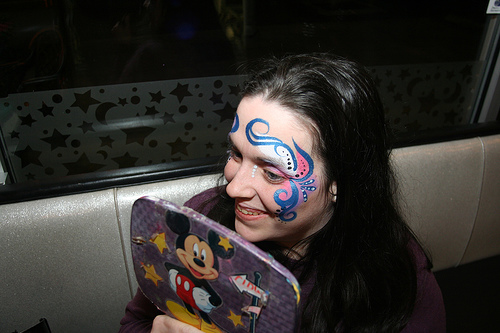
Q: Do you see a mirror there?
A: Yes, there is a mirror.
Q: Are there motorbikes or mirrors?
A: Yes, there is a mirror.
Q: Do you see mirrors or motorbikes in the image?
A: Yes, there is a mirror.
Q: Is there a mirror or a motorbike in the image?
A: Yes, there is a mirror.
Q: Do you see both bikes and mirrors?
A: No, there is a mirror but no bikes.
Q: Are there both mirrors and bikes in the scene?
A: No, there is a mirror but no bikes.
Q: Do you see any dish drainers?
A: No, there are no dish drainers.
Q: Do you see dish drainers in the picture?
A: No, there are no dish drainers.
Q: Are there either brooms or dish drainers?
A: No, there are no dish drainers or brooms.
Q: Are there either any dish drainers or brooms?
A: No, there are no dish drainers or brooms.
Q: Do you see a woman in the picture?
A: Yes, there is a woman.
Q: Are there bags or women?
A: Yes, there is a woman.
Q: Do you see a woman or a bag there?
A: Yes, there is a woman.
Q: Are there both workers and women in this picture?
A: No, there is a woman but no workers.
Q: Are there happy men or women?
A: Yes, there is a happy woman.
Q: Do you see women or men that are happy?
A: Yes, the woman is happy.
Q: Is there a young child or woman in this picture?
A: Yes, there is a young woman.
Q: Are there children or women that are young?
A: Yes, the woman is young.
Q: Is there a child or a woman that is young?
A: Yes, the woman is young.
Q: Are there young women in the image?
A: Yes, there is a young woman.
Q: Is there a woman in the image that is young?
A: Yes, there is a woman that is young.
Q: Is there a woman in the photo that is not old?
A: Yes, there is an young woman.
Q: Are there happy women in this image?
A: Yes, there is a happy woman.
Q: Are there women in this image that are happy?
A: Yes, there is a woman that is happy.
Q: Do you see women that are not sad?
A: Yes, there is a happy woman.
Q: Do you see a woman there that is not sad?
A: Yes, there is a happy woman.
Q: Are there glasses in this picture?
A: No, there are no glasses.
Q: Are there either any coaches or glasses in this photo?
A: No, there are no glasses or coaches.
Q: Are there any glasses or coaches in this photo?
A: No, there are no glasses or coaches.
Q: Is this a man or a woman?
A: This is a woman.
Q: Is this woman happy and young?
A: Yes, the woman is happy and young.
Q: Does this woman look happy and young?
A: Yes, the woman is happy and young.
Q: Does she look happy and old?
A: No, the woman is happy but young.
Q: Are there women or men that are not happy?
A: No, there is a woman but she is happy.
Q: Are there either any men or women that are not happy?
A: No, there is a woman but she is happy.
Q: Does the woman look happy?
A: Yes, the woman is happy.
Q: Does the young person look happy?
A: Yes, the woman is happy.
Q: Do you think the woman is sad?
A: No, the woman is happy.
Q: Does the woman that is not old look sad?
A: No, the woman is happy.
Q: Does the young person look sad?
A: No, the woman is happy.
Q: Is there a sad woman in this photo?
A: No, there is a woman but she is happy.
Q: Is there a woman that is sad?
A: No, there is a woman but she is happy.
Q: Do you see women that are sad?
A: No, there is a woman but she is happy.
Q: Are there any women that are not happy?
A: No, there is a woman but she is happy.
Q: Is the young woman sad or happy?
A: The woman is happy.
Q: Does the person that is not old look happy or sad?
A: The woman is happy.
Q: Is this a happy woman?
A: Yes, this is a happy woman.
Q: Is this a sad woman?
A: No, this is a happy woman.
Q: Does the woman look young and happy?
A: Yes, the woman is young and happy.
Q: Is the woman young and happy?
A: Yes, the woman is young and happy.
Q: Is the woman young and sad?
A: No, the woman is young but happy.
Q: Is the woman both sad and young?
A: No, the woman is young but happy.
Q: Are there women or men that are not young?
A: No, there is a woman but she is young.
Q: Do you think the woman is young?
A: Yes, the woman is young.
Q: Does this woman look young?
A: Yes, the woman is young.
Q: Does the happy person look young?
A: Yes, the woman is young.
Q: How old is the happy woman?
A: The woman is young.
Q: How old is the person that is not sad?
A: The woman is young.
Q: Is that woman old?
A: No, the woman is young.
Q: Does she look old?
A: No, the woman is young.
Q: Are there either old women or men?
A: No, there is a woman but she is young.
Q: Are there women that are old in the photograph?
A: No, there is a woman but she is young.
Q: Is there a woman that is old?
A: No, there is a woman but she is young.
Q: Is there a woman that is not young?
A: No, there is a woman but she is young.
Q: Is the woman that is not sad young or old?
A: The woman is young.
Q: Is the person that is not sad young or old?
A: The woman is young.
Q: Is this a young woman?
A: Yes, this is a young woman.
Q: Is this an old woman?
A: No, this is a young woman.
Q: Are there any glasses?
A: No, there are no glasses.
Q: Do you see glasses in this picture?
A: No, there are no glasses.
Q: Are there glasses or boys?
A: No, there are no glasses or boys.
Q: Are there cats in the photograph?
A: No, there are no cats.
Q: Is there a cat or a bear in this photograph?
A: No, there are no cats or bears.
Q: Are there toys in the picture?
A: No, there are no toys.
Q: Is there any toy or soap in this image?
A: No, there are no toys or soaps.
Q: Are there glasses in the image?
A: No, there are no glasses.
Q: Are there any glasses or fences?
A: No, there are no glasses or fences.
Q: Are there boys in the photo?
A: No, there are no boys.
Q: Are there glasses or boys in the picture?
A: No, there are no boys or glasses.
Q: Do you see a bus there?
A: No, there are no buses.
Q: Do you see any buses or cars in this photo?
A: No, there are no buses or cars.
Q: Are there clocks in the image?
A: No, there are no clocks.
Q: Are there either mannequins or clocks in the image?
A: No, there are no clocks or mannequins.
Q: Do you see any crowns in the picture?
A: No, there are no crowns.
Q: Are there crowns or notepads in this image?
A: No, there are no crowns or notepads.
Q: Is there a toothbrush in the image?
A: No, there are no toothbrushes.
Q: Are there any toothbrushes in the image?
A: No, there are no toothbrushes.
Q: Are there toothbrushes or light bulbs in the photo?
A: No, there are no toothbrushes or light bulbs.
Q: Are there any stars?
A: Yes, there is a star.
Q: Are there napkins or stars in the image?
A: Yes, there is a star.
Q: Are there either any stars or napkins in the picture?
A: Yes, there is a star.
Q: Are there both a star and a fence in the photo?
A: No, there is a star but no fences.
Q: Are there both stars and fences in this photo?
A: No, there is a star but no fences.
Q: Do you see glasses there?
A: No, there are no glasses.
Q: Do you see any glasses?
A: No, there are no glasses.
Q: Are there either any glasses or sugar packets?
A: No, there are no glasses or sugar packets.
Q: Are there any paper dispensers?
A: No, there are no paper dispensers.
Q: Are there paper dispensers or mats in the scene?
A: No, there are no paper dispensers or mats.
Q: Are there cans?
A: No, there are no cans.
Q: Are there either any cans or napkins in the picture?
A: No, there are no cans or napkins.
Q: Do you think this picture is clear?
A: Yes, the picture is clear.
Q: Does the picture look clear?
A: Yes, the picture is clear.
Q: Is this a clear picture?
A: Yes, this is a clear picture.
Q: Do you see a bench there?
A: Yes, there is a bench.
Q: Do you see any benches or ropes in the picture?
A: Yes, there is a bench.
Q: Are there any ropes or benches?
A: Yes, there is a bench.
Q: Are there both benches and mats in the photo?
A: No, there is a bench but no mats.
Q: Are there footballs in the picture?
A: No, there are no footballs.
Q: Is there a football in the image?
A: No, there are no footballs.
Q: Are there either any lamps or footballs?
A: No, there are no footballs or lamps.